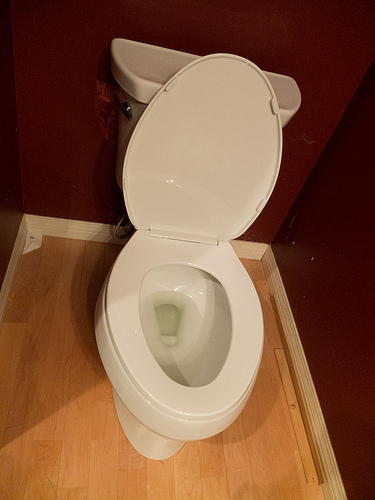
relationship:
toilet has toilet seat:
[91, 36, 300, 461] [103, 229, 266, 419]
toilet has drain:
[91, 36, 300, 461] [151, 297, 185, 344]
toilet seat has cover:
[103, 229, 266, 419] [120, 51, 283, 245]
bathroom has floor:
[1, 1, 374, 500] [1, 233, 327, 499]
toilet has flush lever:
[91, 36, 300, 461] [111, 88, 133, 123]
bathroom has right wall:
[1, 1, 374, 500] [1, 2, 24, 295]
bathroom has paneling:
[1, 1, 374, 500] [2, 211, 349, 499]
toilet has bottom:
[91, 36, 300, 461] [109, 382, 188, 461]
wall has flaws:
[1, 0, 374, 499] [93, 77, 121, 148]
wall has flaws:
[1, 0, 374, 499] [287, 128, 318, 152]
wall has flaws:
[1, 0, 374, 499] [285, 208, 316, 302]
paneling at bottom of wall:
[2, 211, 349, 499] [1, 0, 374, 499]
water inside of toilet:
[143, 286, 200, 361] [91, 36, 300, 461]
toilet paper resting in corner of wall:
[19, 224, 46, 260] [1, 0, 374, 499]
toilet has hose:
[91, 36, 300, 461] [111, 207, 134, 241]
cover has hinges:
[120, 51, 283, 245] [159, 77, 181, 96]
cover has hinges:
[120, 51, 283, 245] [267, 95, 282, 119]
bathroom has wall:
[1, 1, 374, 500] [1, 0, 374, 499]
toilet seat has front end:
[103, 229, 266, 419] [140, 380, 244, 420]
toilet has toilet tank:
[91, 36, 300, 461] [106, 35, 301, 192]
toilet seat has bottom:
[103, 229, 266, 419] [109, 382, 188, 461]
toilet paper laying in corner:
[19, 224, 46, 260] [15, 208, 54, 265]